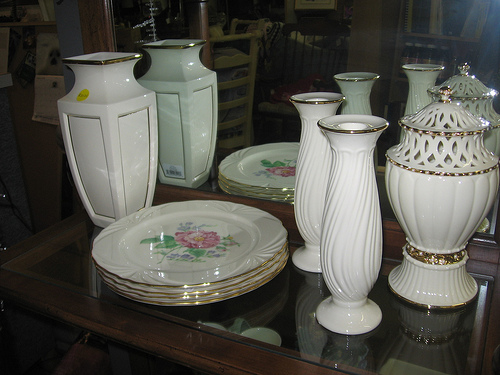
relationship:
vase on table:
[65, 55, 161, 221] [4, 191, 484, 375]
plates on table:
[92, 199, 291, 306] [4, 191, 484, 375]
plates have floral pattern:
[92, 199, 291, 306] [157, 227, 221, 257]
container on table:
[398, 90, 484, 309] [4, 191, 484, 375]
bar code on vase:
[159, 167, 187, 178] [65, 55, 161, 221]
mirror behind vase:
[114, 3, 499, 230] [65, 55, 161, 221]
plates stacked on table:
[92, 199, 291, 306] [4, 191, 484, 375]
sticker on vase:
[78, 87, 89, 101] [65, 55, 161, 221]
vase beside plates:
[65, 55, 161, 221] [92, 199, 291, 306]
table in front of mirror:
[4, 191, 484, 375] [114, 3, 499, 230]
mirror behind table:
[114, 3, 499, 230] [4, 191, 484, 375]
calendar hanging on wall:
[31, 36, 76, 129] [1, 28, 79, 152]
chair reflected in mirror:
[270, 23, 333, 106] [114, 3, 499, 230]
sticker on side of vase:
[78, 87, 89, 101] [65, 55, 161, 221]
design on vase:
[397, 133, 486, 165] [398, 90, 484, 309]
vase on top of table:
[287, 93, 334, 272] [4, 191, 484, 375]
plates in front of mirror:
[92, 199, 291, 306] [114, 3, 499, 230]